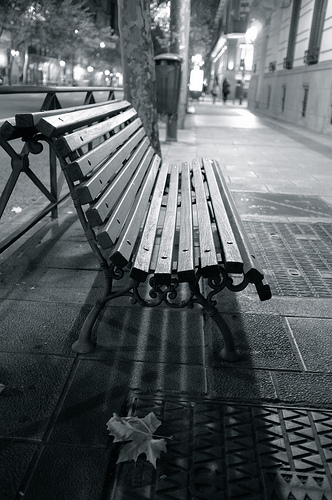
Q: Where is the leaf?
A: Sidewalk.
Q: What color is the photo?
A: Black and white.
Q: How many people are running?
A: 0.